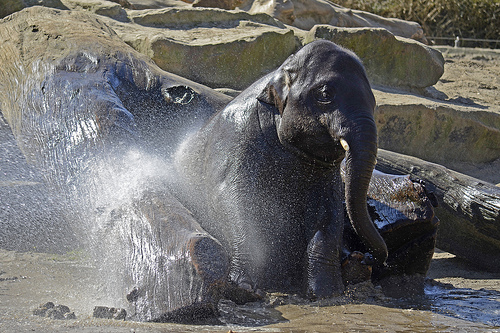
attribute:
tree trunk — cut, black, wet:
[2, 7, 495, 333]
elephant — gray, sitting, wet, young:
[170, 40, 388, 299]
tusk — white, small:
[336, 132, 353, 155]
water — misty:
[0, 115, 499, 329]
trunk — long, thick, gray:
[328, 114, 395, 259]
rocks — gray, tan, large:
[62, 4, 500, 183]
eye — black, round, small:
[315, 82, 335, 103]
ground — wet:
[1, 199, 497, 331]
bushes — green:
[328, 0, 499, 48]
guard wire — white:
[427, 34, 498, 49]